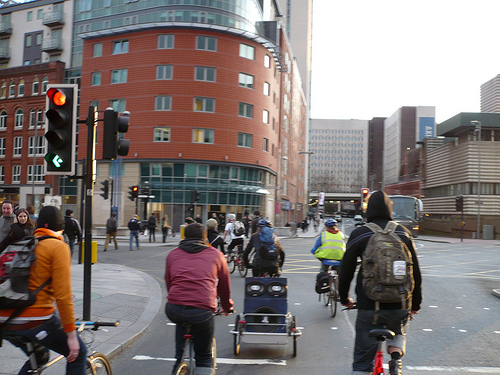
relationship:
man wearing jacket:
[25, 224, 109, 365] [8, 236, 125, 316]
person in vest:
[315, 217, 342, 317] [320, 228, 345, 256]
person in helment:
[315, 217, 342, 317] [322, 215, 339, 227]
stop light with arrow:
[40, 77, 172, 157] [46, 151, 71, 176]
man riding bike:
[0, 206, 88, 374] [2, 321, 120, 372]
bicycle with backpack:
[358, 311, 400, 373] [361, 233, 411, 294]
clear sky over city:
[320, 5, 483, 117] [12, 17, 477, 348]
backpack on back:
[8, 244, 42, 310] [35, 256, 47, 288]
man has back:
[0, 206, 88, 374] [35, 256, 47, 288]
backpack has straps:
[8, 244, 42, 310] [17, 229, 54, 252]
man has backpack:
[334, 183, 432, 368] [367, 224, 414, 305]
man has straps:
[0, 206, 88, 374] [32, 275, 56, 306]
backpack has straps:
[367, 224, 414, 305] [363, 218, 399, 231]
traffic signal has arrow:
[43, 75, 74, 177] [47, 155, 66, 170]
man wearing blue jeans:
[0, 206, 88, 374] [162, 301, 222, 370]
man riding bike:
[0, 206, 88, 374] [2, 306, 120, 372]